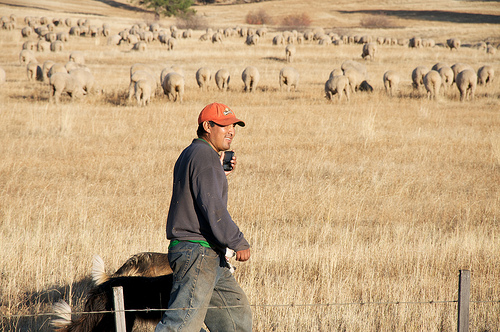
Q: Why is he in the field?
A: Herding the animals.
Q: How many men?
A: One.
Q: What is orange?
A: His hat.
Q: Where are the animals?
A: In the field.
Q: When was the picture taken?
A: Daytime.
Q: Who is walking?
A: Man.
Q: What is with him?
A: A dog.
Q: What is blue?
A: Jeans.